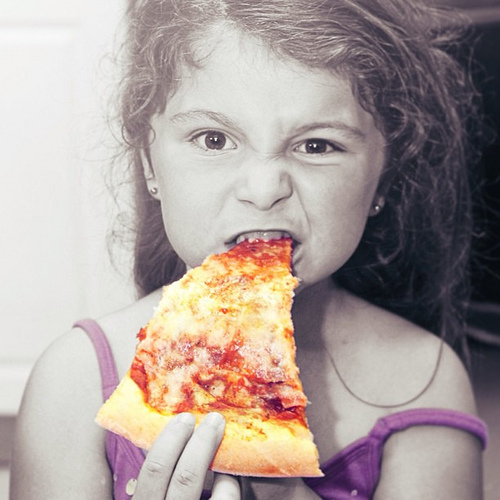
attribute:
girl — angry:
[111, 39, 389, 477]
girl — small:
[80, 48, 399, 449]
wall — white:
[15, 127, 75, 243]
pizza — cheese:
[115, 256, 320, 445]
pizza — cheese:
[91, 218, 321, 464]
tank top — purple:
[38, 322, 417, 497]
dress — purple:
[74, 316, 488, 498]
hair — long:
[80, 1, 483, 381]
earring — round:
[148, 184, 162, 196]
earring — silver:
[147, 184, 158, 200]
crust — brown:
[91, 373, 326, 480]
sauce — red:
[131, 326, 310, 426]